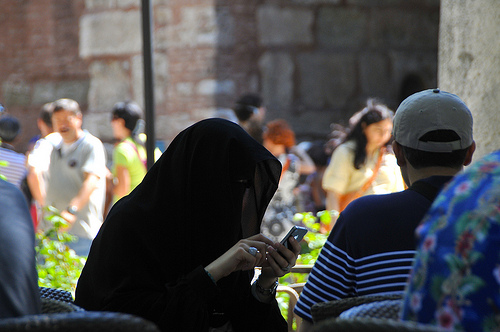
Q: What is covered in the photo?
A: Woman in black.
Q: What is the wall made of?
A: Stone.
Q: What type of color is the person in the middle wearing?
A: Black.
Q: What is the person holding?
A: Cell phone.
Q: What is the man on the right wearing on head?
A: Cap.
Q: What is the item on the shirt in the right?
A: Flowered.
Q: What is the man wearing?
A: Hat.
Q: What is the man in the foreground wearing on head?
A: A hat.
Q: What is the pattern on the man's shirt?
A: Striped.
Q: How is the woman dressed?
A: In black.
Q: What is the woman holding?
A: A phone.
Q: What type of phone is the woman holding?
A: IPhone.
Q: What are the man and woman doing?
A: Sitting.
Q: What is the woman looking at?
A: Phone.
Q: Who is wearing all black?
A: The woman.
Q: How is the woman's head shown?
A: Covered.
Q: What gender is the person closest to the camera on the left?
A: Female.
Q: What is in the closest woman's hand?
A: Cellphone.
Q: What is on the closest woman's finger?
A: Ring.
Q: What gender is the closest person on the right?
A: Male.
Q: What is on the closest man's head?
A: Cap.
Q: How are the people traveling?
A: Walking.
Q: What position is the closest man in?
A: Sitting.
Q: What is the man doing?
A: Standing.